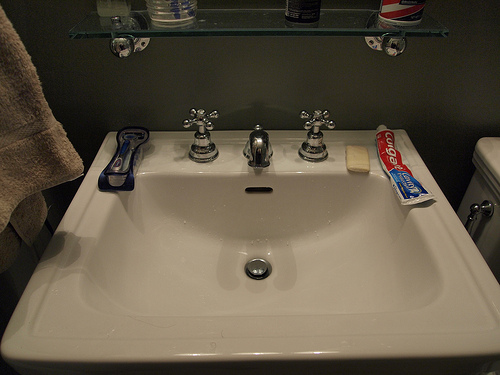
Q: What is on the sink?
A: Toothpaste.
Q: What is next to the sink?
A: A towel.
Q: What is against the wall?
A: A sink.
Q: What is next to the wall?
A: A sink.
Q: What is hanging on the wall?
A: A towel.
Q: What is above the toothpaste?
A: Shelf above sink.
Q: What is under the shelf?
A: Toiletries on sink.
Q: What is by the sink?
A: Brown towel.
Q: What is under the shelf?
A: White square sink.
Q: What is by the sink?
A: Tan towel.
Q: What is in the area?
A: Bathroom with hygiene stuff.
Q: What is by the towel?
A: Shelf above sink.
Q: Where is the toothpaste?
A: On the sink.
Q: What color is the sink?
A: White.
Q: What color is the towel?
A: Brown.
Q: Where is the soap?
A: Next to the toothpaste.